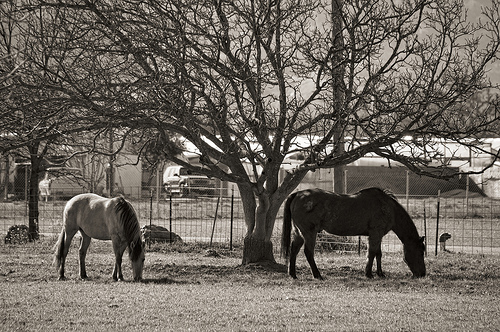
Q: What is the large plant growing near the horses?
A: A tree.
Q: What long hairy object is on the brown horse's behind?
A: A tail.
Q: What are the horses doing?
A: Grazing on grass.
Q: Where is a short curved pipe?
A: Outside the fence.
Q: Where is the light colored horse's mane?
A: On its neck.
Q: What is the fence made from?
A: Metal wire.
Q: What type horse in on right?
A: Dark brown horse.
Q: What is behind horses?
A: A metal fence.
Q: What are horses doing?
A: Eating grass.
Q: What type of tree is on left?
A: Small leafless.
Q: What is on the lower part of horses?
A: Legs.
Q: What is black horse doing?
A: Walking and grazing.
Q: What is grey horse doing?
A: Grazing.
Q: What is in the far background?
A: Trucks.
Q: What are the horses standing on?
A: Grassy field.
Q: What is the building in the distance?
A: Barn.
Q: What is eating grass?
A: Horse.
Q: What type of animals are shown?
A: Horses.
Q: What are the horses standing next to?
A: Tree.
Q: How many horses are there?
A: Two.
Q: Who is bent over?
A: Horses.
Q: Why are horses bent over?
A: To eat the grass.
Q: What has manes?
A: The horses.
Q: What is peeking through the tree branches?
A: The sky.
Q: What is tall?
A: A tree.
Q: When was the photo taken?
A: Daytime.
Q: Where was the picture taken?
A: In the horse pasture.